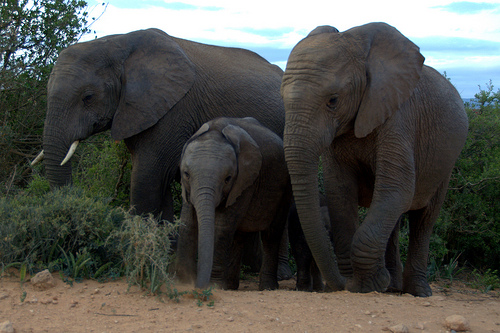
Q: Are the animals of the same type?
A: Yes, all the animals are elephants.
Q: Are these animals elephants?
A: Yes, all the animals are elephants.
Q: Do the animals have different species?
A: No, all the animals are elephants.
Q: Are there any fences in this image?
A: No, there are no fences.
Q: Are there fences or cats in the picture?
A: No, there are no fences or cats.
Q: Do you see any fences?
A: No, there are no fences.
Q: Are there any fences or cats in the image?
A: No, there are no fences or cats.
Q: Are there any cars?
A: No, there are no cars.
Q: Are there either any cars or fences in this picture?
A: No, there are no cars or fences.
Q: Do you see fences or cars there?
A: No, there are no cars or fences.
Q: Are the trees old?
A: Yes, the trees are old.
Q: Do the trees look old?
A: Yes, the trees are old.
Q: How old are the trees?
A: The trees are old.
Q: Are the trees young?
A: No, the trees are old.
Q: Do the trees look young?
A: No, the trees are old.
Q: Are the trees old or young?
A: The trees are old.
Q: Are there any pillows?
A: No, there are no pillows.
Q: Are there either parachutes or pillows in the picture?
A: No, there are no pillows or parachutes.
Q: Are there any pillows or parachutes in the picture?
A: No, there are no pillows or parachutes.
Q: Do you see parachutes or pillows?
A: No, there are no pillows or parachutes.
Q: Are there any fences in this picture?
A: No, there are no fences.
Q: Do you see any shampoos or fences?
A: No, there are no fences or shampoos.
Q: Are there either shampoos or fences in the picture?
A: No, there are no fences or shampoos.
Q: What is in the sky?
A: The clouds are in the sky.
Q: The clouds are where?
A: The clouds are in the sky.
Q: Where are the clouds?
A: The clouds are in the sky.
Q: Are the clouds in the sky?
A: Yes, the clouds are in the sky.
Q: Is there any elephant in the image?
A: Yes, there are elephants.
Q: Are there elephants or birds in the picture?
A: Yes, there are elephants.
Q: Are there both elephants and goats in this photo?
A: No, there are elephants but no goats.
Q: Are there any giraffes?
A: No, there are no giraffes.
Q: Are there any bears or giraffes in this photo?
A: No, there are no giraffes or bears.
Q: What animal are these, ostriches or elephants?
A: These are elephants.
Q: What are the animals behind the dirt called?
A: The animals are elephants.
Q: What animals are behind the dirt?
A: The animals are elephants.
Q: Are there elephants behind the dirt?
A: Yes, there are elephants behind the dirt.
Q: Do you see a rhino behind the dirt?
A: No, there are elephants behind the dirt.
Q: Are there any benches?
A: No, there are no benches.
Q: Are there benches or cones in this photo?
A: No, there are no benches or cones.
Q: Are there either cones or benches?
A: No, there are no benches or cones.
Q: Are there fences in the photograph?
A: No, there are no fences.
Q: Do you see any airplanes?
A: No, there are no airplanes.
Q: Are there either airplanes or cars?
A: No, there are no airplanes or cars.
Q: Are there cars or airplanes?
A: No, there are no airplanes or cars.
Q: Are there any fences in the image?
A: No, there are no fences.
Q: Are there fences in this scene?
A: No, there are no fences.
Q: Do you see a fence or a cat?
A: No, there are no fences or cats.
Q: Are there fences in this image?
A: No, there are no fences.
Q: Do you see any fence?
A: No, there are no fences.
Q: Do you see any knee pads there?
A: No, there are no knee pads.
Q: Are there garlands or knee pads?
A: No, there are no knee pads or garlands.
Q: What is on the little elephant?
A: The trunk is on the elephant.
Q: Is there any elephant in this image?
A: Yes, there is an elephant.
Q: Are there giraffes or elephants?
A: Yes, there is an elephant.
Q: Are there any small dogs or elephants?
A: Yes, there is a small elephant.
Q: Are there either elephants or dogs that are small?
A: Yes, the elephant is small.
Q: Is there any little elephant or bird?
A: Yes, there is a little elephant.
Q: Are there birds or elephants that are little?
A: Yes, the elephant is little.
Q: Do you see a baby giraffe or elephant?
A: Yes, there is a baby elephant.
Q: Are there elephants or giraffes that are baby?
A: Yes, the elephant is a baby.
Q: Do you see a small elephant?
A: Yes, there is a small elephant.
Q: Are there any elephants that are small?
A: Yes, there is a small elephant.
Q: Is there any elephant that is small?
A: Yes, there is an elephant that is small.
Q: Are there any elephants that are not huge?
A: Yes, there is a small elephant.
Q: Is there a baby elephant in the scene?
A: Yes, there is a baby elephant.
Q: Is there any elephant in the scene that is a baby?
A: Yes, there is an elephant that is a baby.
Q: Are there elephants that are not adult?
A: Yes, there is an baby elephant.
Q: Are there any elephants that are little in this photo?
A: Yes, there is a little elephant.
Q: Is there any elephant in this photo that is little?
A: Yes, there is an elephant that is little.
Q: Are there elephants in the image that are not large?
A: Yes, there is a little elephant.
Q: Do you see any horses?
A: No, there are no horses.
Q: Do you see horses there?
A: No, there are no horses.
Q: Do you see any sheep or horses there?
A: No, there are no horses or sheep.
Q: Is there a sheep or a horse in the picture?
A: No, there are no horses or sheep.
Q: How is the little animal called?
A: The animal is an elephant.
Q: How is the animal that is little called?
A: The animal is an elephant.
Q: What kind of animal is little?
A: The animal is an elephant.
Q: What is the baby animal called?
A: The animal is an elephant.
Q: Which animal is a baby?
A: The animal is an elephant.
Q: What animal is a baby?
A: The animal is an elephant.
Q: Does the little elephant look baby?
A: Yes, the elephant is a baby.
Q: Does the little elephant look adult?
A: No, the elephant is a baby.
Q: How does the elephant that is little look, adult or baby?
A: The elephant is a baby.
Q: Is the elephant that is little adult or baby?
A: The elephant is a baby.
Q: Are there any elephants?
A: Yes, there is an elephant.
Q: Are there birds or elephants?
A: Yes, there is an elephant.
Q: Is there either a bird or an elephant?
A: Yes, there is an elephant.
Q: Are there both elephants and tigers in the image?
A: No, there is an elephant but no tigers.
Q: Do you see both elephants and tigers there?
A: No, there is an elephant but no tigers.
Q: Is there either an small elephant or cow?
A: Yes, there is a small elephant.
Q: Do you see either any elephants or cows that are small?
A: Yes, the elephant is small.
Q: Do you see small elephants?
A: Yes, there is a small elephant.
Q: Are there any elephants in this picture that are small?
A: Yes, there is an elephant that is small.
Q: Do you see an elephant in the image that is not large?
A: Yes, there is a small elephant.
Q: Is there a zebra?
A: No, there are no zebras.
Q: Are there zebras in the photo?
A: No, there are no zebras.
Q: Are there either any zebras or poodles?
A: No, there are no zebras or poodles.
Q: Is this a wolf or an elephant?
A: This is an elephant.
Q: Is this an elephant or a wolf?
A: This is an elephant.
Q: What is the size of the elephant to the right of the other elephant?
A: The elephant is small.